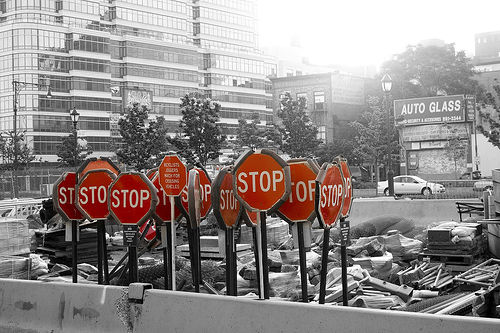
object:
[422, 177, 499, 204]
gate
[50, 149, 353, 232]
pizza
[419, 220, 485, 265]
stack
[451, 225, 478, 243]
sand bag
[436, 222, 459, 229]
sand bag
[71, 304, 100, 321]
stain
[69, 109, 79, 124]
light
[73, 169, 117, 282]
signs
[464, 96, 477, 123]
sign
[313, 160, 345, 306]
sign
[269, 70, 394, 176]
building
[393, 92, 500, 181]
building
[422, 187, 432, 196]
tire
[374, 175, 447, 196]
car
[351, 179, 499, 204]
floor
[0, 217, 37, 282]
pallet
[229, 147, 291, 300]
sign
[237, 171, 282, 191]
letters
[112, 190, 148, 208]
letters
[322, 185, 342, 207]
letters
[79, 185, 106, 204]
letters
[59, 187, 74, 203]
letters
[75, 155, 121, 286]
signs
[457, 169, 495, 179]
truck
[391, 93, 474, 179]
business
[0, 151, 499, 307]
supplies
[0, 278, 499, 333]
cement barracade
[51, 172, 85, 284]
signs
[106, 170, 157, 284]
signs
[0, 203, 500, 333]
small bridge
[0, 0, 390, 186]
buildings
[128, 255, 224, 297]
rolls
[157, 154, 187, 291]
signs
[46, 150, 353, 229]
stop signs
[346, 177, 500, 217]
bridge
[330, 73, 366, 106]
sign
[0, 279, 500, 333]
bridge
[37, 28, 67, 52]
window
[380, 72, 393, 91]
street lamp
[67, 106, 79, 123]
street lamp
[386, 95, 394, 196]
black pole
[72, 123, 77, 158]
black pole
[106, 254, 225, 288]
fence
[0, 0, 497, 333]
yard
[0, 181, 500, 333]
ground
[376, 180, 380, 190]
taillight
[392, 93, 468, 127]
advertisement sign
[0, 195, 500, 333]
enclosed area